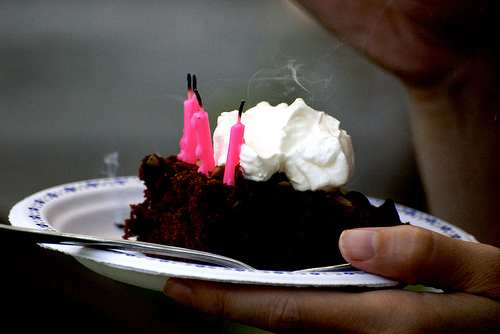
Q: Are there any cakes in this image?
A: Yes, there is a cake.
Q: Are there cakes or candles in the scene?
A: Yes, there is a cake.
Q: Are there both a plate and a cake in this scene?
A: Yes, there are both a cake and a plate.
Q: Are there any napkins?
A: No, there are no napkins.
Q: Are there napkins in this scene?
A: No, there are no napkins.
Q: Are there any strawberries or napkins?
A: No, there are no napkins or strawberries.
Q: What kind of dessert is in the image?
A: The dessert is a cake.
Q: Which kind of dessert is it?
A: The dessert is a cake.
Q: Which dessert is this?
A: This is a cake.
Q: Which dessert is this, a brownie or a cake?
A: This is a cake.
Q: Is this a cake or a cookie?
A: This is a cake.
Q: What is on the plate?
A: The cake is on the plate.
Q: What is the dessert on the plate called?
A: The dessert is a cake.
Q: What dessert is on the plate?
A: The dessert is a cake.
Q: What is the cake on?
A: The cake is on the plate.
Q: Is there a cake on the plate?
A: Yes, there is a cake on the plate.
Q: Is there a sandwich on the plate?
A: No, there is a cake on the plate.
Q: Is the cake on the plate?
A: Yes, the cake is on the plate.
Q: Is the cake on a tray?
A: No, the cake is on the plate.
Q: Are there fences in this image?
A: No, there are no fences.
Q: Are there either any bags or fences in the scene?
A: No, there are no fences or bags.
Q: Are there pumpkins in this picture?
A: No, there are no pumpkins.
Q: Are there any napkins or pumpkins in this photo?
A: No, there are no pumpkins or napkins.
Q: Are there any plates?
A: Yes, there is a plate.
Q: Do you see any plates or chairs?
A: Yes, there is a plate.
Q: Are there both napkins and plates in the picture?
A: No, there is a plate but no napkins.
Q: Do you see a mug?
A: No, there are no mugs.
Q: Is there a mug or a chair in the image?
A: No, there are no mugs or chairs.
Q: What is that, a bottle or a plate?
A: That is a plate.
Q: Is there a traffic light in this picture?
A: No, there are no traffic lights.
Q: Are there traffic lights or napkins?
A: No, there are no traffic lights or napkins.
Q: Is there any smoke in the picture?
A: Yes, there is smoke.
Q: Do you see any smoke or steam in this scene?
A: Yes, there is smoke.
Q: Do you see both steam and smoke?
A: No, there is smoke but no steam.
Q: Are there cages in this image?
A: No, there are no cages.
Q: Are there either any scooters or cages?
A: No, there are no cages or scooters.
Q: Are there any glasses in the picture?
A: No, there are no glasses.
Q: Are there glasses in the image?
A: No, there are no glasses.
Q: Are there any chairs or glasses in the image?
A: No, there are no glasses or chairs.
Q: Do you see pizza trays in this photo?
A: No, there are no pizza trays.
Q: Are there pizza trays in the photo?
A: No, there are no pizza trays.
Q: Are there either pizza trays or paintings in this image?
A: No, there are no pizza trays or paintings.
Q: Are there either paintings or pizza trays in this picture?
A: No, there are no pizza trays or paintings.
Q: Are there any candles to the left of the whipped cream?
A: Yes, there is a candle to the left of the whipped cream.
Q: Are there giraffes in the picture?
A: No, there are no giraffes.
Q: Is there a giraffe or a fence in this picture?
A: No, there are no giraffes or fences.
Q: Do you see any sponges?
A: No, there are no sponges.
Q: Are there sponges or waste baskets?
A: No, there are no sponges or waste baskets.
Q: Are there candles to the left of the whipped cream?
A: Yes, there is a candle to the left of the whipped cream.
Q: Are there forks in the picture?
A: Yes, there is a fork.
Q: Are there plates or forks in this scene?
A: Yes, there is a fork.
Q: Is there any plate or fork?
A: Yes, there is a fork.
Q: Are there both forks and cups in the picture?
A: No, there is a fork but no cups.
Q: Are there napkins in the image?
A: No, there are no napkins.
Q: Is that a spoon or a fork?
A: That is a fork.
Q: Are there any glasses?
A: No, there are no glasses.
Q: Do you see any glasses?
A: No, there are no glasses.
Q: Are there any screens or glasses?
A: No, there are no glasses or screens.